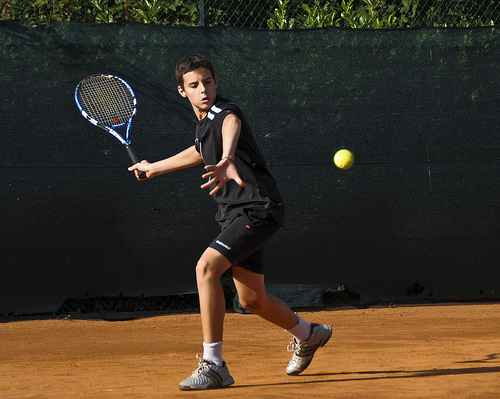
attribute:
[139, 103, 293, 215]
shirt — black 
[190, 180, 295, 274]
shorts — black 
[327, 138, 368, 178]
tennis ball — flying 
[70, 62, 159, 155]
racket — blue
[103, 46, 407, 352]
man — holding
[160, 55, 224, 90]
hair — black, man's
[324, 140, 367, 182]
tennis ball — yellow 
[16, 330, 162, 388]
dirt ground — dirt 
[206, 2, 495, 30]
fence — green  , chain link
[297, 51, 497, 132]
green screen — green 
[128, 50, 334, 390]
tennis player — male 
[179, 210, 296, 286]
black shorts — black 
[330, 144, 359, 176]
tennis ball — yellow 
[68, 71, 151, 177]
tennis racket — blue, black , white 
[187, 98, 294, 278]
black outfit — black 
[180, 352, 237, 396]
tennis shoe — gray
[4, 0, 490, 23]
foliage — green 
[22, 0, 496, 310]
fence — chain link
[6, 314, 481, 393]
ground — brown 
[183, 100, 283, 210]
tank top — black 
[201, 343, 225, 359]
white socks — white 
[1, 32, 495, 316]
black cover — black 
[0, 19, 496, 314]
fence — chain link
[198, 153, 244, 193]
left hand — open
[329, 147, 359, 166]
tennis ball — green 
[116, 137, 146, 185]
black handle — black 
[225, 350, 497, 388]
black shadow — black 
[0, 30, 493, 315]
green tarp — green 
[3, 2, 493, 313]
metal fence — metal 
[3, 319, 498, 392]
tennis court — brown 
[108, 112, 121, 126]
dot — red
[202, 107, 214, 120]
stripe — white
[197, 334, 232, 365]
sock — white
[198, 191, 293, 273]
shorts — black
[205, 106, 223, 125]
stripe — white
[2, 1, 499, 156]
leaves — green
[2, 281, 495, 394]
dirt — brown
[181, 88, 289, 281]
outfit — black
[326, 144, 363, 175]
ball — yellow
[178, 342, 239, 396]
shoe — gray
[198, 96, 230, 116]
stripe — white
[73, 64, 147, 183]
racket — blue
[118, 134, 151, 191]
handle — black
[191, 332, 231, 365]
sock — white